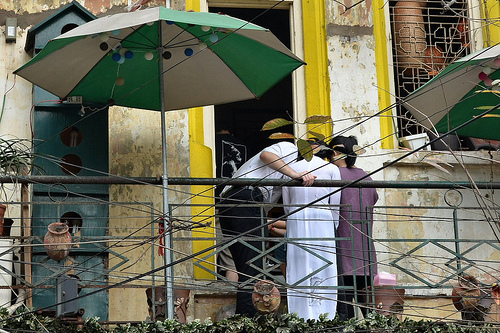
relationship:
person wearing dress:
[281, 130, 339, 311] [272, 206, 322, 303]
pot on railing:
[40, 222, 73, 253] [80, 177, 161, 185]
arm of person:
[258, 150, 290, 173] [281, 130, 339, 311]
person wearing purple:
[281, 130, 339, 311] [343, 178, 361, 203]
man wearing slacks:
[225, 132, 289, 219] [216, 198, 267, 268]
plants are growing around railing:
[1, 155, 42, 172] [80, 177, 161, 185]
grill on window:
[404, 8, 451, 47] [386, 0, 486, 150]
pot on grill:
[40, 222, 73, 253] [404, 8, 451, 47]